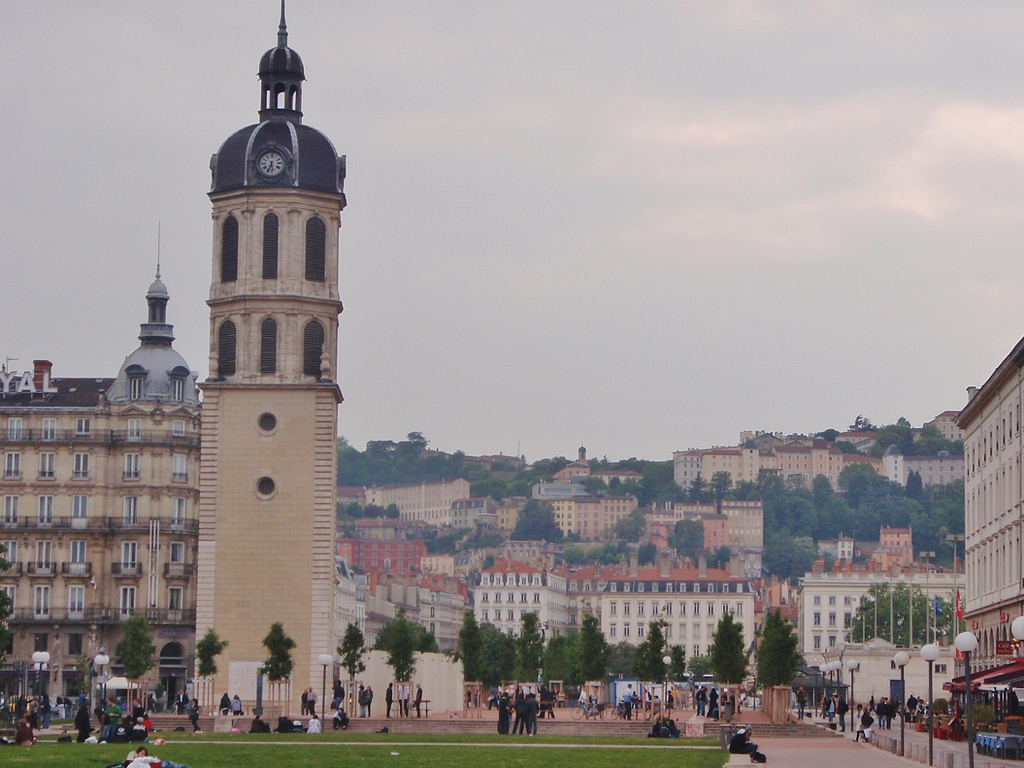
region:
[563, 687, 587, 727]
The woman is holding a large orange.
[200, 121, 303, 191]
clock on the top of the building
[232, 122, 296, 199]
the face of the clock is white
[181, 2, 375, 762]
the clock tower is huge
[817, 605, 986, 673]
the lights are round balls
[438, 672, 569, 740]
people standing in a huddle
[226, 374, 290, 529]
2 small circles on the building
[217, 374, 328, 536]
the circles are black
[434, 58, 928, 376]
the sky is partly cloudy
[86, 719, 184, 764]
person sitting on the grass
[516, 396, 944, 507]
buildings on the top of the hill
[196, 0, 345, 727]
stone clock tower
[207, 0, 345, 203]
dome and clock of the clock tower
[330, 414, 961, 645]
city hill in the distance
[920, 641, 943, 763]
a white dome street light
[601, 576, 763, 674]
a building with a dark roof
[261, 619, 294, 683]
the green leaves of a tree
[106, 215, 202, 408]
the grey dome of a building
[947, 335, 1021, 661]
the side of an old building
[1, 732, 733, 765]
green grass in a city park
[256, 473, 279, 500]
a round window in a building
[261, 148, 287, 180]
a clock on the roof of a tower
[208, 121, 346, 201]
domed roof on a tower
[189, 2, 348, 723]
tall tower attached to a building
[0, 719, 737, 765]
a courtyard in front of a building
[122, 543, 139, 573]
window on a building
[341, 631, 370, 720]
thin tree in front of a buiding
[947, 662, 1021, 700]
a red awning on a building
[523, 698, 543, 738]
a person in a courtyard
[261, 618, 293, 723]
tall skinny green tree in front of white tower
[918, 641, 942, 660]
white globe on black utility pole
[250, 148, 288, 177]
white clock on large black dome roof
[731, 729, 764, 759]
person in black sits on concrete curb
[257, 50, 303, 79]
a circular object on tower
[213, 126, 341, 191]
dome on the tower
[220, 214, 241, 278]
window on the tower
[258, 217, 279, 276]
window on the tower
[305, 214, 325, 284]
window on the tower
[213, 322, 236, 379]
window on the tower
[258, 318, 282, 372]
window on the tower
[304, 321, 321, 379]
window on the tower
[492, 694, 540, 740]
people are standing around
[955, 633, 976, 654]
the bulb is white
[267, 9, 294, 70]
the spire is on top of the dome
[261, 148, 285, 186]
clock in the top of a tower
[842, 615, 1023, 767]
street lights with round white globes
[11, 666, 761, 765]
people gathered in a grassy area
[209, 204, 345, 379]
two floors of arched windows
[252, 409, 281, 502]
two small round windows in the tower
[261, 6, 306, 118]
small belfry on thop of the tower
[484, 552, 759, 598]
red tiled roof with many chimneys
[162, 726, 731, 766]
sidewalk through a grassy area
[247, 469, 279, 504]
circular window on side of tan building tower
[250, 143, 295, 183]
clock on top of tower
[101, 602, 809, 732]
line of tall green trees in front of tan building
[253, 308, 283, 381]
arched window on top of tan building tower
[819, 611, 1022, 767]
line of black and white street lamps on sidewalk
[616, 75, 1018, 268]
white cloud in blue sky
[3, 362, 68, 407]
large white metal structures shaped like letters on building roof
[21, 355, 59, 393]
red chimney on roof